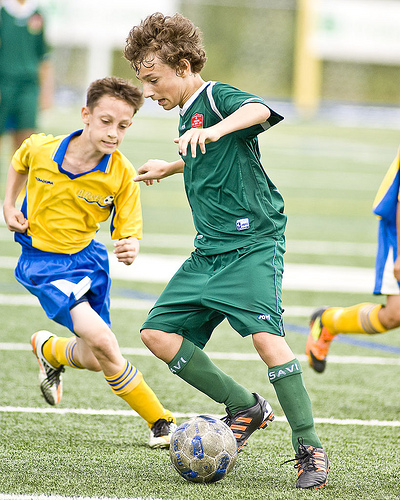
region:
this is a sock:
[262, 340, 337, 470]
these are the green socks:
[148, 323, 334, 457]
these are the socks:
[32, 311, 328, 463]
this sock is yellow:
[95, 355, 193, 440]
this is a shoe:
[282, 433, 350, 498]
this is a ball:
[138, 393, 247, 479]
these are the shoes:
[2, 315, 346, 496]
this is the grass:
[63, 440, 97, 464]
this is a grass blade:
[126, 469, 132, 477]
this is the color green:
[219, 284, 229, 290]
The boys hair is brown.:
[124, 9, 211, 109]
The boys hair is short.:
[124, 11, 206, 113]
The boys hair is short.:
[83, 71, 143, 157]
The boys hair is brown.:
[81, 73, 146, 155]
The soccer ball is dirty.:
[168, 415, 235, 481]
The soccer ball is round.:
[167, 418, 240, 484]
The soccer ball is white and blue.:
[167, 415, 244, 484]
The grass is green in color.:
[18, 436, 87, 490]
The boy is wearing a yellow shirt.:
[3, 136, 144, 258]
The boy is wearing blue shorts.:
[12, 240, 129, 330]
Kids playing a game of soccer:
[4, 9, 335, 492]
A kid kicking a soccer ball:
[115, 10, 345, 494]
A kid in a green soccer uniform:
[126, 12, 332, 487]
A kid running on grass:
[10, 65, 178, 453]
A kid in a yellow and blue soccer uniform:
[14, 75, 179, 455]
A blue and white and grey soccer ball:
[168, 412, 236, 485]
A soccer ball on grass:
[165, 411, 234, 490]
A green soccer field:
[0, 100, 394, 497]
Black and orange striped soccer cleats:
[219, 391, 332, 489]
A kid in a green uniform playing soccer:
[123, 7, 333, 490]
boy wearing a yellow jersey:
[36, 66, 141, 290]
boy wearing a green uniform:
[125, 18, 340, 330]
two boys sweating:
[36, 9, 285, 182]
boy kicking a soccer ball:
[156, 133, 348, 487]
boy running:
[21, 89, 144, 435]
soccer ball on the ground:
[161, 405, 244, 484]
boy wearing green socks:
[144, 321, 336, 417]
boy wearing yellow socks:
[43, 321, 151, 493]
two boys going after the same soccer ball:
[31, 17, 332, 492]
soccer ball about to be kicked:
[170, 406, 323, 496]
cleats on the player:
[293, 445, 333, 482]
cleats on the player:
[221, 400, 264, 445]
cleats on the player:
[144, 423, 171, 447]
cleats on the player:
[25, 337, 62, 411]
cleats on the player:
[300, 317, 346, 384]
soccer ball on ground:
[171, 416, 241, 490]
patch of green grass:
[41, 456, 63, 472]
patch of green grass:
[340, 459, 355, 475]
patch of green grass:
[354, 391, 386, 408]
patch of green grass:
[34, 415, 58, 430]